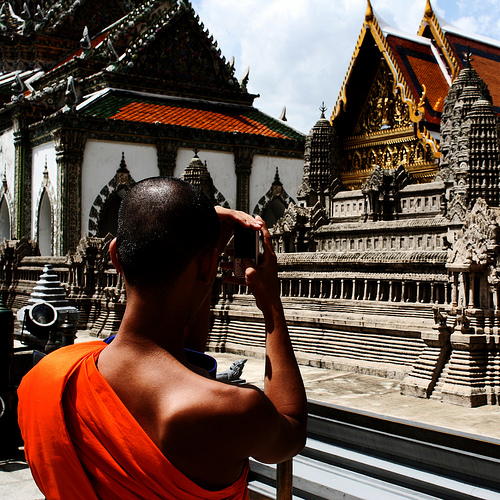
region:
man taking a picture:
[19, 158, 339, 499]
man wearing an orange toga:
[12, 173, 342, 496]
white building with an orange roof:
[4, 2, 321, 292]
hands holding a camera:
[214, 203, 283, 288]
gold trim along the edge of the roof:
[361, 21, 419, 114]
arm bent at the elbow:
[197, 251, 332, 474]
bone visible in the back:
[155, 397, 193, 452]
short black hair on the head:
[105, 178, 207, 302]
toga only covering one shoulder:
[7, 325, 267, 498]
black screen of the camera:
[229, 221, 257, 256]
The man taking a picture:
[15, 178, 306, 498]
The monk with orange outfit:
[16, 176, 308, 498]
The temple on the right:
[273, 1, 498, 497]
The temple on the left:
[0, 0, 308, 352]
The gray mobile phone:
[233, 213, 257, 280]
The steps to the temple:
[202, 379, 499, 499]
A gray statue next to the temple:
[20, 264, 80, 350]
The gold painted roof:
[324, 0, 460, 195]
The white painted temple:
[2, 139, 307, 259]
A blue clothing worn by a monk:
[34, 335, 219, 383]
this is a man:
[66, 182, 287, 497]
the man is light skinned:
[133, 334, 166, 400]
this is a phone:
[234, 230, 251, 254]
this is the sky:
[245, 14, 305, 91]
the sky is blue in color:
[455, 3, 494, 28]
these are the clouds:
[263, 17, 310, 44]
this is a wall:
[91, 144, 108, 169]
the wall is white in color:
[90, 145, 108, 173]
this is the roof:
[113, 98, 218, 116]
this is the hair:
[128, 238, 153, 281]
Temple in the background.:
[289, 23, 499, 393]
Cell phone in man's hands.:
[226, 211, 263, 291]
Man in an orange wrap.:
[18, 168, 305, 498]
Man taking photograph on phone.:
[17, 165, 316, 498]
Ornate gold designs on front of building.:
[333, 31, 439, 183]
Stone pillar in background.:
[27, 261, 74, 315]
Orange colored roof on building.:
[106, 89, 278, 142]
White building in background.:
[1, 91, 308, 283]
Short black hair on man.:
[98, 168, 228, 323]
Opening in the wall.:
[30, 158, 64, 255]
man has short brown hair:
[98, 169, 209, 296]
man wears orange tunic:
[10, 347, 176, 499]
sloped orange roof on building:
[370, 22, 498, 138]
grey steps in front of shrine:
[256, 285, 429, 401]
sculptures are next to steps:
[431, 198, 499, 396]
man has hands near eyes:
[139, 175, 272, 303]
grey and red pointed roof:
[65, 6, 297, 173]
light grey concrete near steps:
[321, 362, 431, 443]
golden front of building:
[327, 43, 441, 196]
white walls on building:
[20, 140, 329, 262]